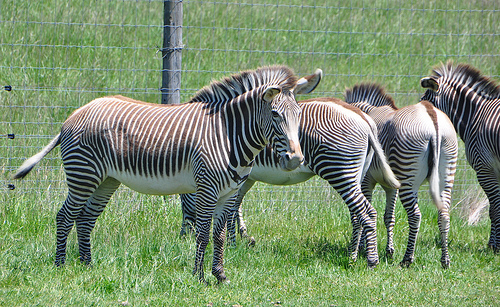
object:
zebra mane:
[189, 64, 300, 103]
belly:
[102, 166, 197, 197]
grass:
[1, 0, 498, 306]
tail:
[369, 128, 401, 189]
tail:
[427, 131, 444, 210]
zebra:
[340, 80, 460, 270]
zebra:
[10, 63, 322, 285]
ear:
[417, 75, 440, 89]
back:
[69, 92, 226, 124]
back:
[295, 92, 358, 118]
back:
[369, 97, 443, 123]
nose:
[279, 153, 309, 166]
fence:
[0, 0, 499, 203]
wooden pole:
[159, 0, 185, 108]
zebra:
[177, 98, 406, 273]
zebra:
[417, 52, 500, 256]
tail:
[14, 125, 64, 179]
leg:
[53, 165, 110, 266]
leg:
[74, 179, 122, 266]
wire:
[0, 16, 498, 38]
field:
[1, 0, 499, 305]